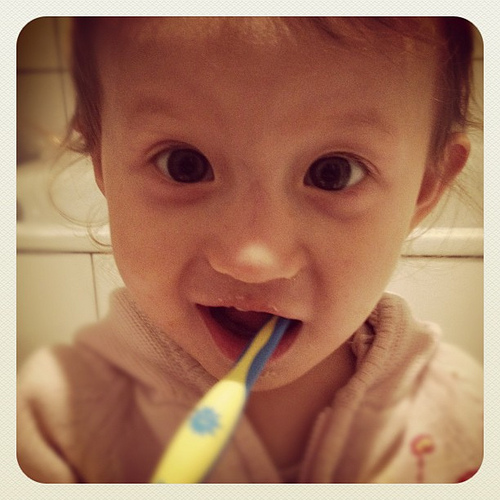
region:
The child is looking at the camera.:
[146, 138, 376, 193]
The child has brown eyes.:
[148, 143, 366, 192]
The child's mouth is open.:
[194, 293, 249, 335]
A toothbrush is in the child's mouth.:
[149, 315, 290, 484]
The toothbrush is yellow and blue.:
[145, 314, 290, 482]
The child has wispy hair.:
[437, 78, 474, 130]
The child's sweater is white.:
[377, 352, 463, 462]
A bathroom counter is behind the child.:
[13, 235, 86, 323]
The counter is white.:
[17, 238, 90, 323]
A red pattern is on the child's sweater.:
[407, 433, 434, 483]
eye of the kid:
[141, 143, 211, 196]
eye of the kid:
[305, 156, 363, 208]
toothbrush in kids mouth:
[131, 342, 296, 499]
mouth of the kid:
[157, 295, 294, 364]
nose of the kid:
[151, 218, 318, 283]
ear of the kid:
[440, 133, 462, 222]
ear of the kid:
[78, 117, 115, 207]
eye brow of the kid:
[123, 91, 189, 118]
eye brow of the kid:
[331, 110, 381, 142]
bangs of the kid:
[208, 20, 347, 54]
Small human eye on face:
[285, 118, 388, 230]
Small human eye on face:
[105, 106, 219, 218]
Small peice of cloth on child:
[385, 298, 439, 346]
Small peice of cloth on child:
[435, 328, 475, 390]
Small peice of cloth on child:
[365, 348, 479, 453]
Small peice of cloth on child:
[324, 405, 421, 476]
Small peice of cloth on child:
[80, 285, 147, 349]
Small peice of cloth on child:
[30, 337, 122, 400]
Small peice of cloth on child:
[120, 367, 205, 413]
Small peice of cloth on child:
[40, 402, 135, 485]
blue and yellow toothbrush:
[155, 314, 287, 481]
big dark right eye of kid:
[144, 140, 212, 191]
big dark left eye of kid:
[305, 150, 380, 198]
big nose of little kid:
[213, 188, 313, 292]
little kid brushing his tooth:
[17, 17, 481, 479]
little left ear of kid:
[416, 131, 468, 227]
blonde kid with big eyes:
[19, 15, 483, 481]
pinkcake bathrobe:
[29, 290, 479, 487]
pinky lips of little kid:
[197, 295, 307, 366]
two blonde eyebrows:
[116, 99, 411, 145]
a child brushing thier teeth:
[68, 73, 494, 498]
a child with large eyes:
[73, 44, 492, 462]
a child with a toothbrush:
[43, 152, 395, 492]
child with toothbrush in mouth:
[75, 243, 385, 485]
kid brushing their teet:
[43, 248, 482, 498]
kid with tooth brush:
[92, 247, 372, 479]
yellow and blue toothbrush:
[85, 259, 482, 499]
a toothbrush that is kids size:
[186, 306, 357, 486]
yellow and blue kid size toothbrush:
[126, 303, 462, 498]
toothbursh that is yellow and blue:
[89, 273, 400, 499]